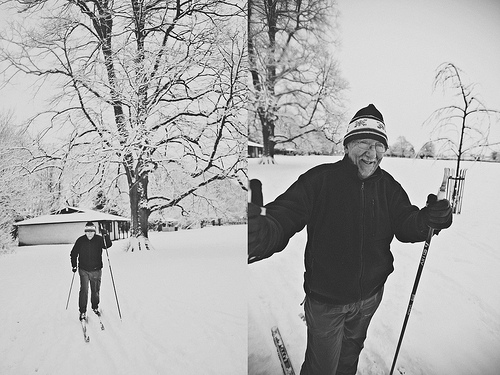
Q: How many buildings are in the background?
A: One.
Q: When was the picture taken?
A: Day time.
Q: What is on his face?
A: Glasses.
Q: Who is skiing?
A: A man.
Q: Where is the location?
A: Ski resort.